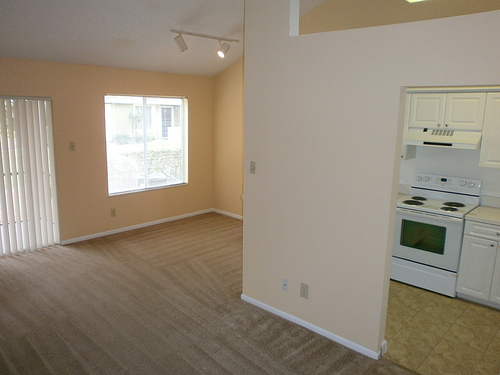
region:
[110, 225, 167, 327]
the floor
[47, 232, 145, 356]
the floor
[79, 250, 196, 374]
the floor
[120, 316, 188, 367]
the floor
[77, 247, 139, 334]
the floor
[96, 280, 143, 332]
the floor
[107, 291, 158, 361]
the floor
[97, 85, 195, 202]
a window on the wall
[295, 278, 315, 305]
an electrical socket on the wall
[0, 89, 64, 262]
a doorway in the room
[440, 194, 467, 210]
a black burner on the stove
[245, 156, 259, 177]
a light switch on the wall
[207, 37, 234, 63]
a lit ceiling light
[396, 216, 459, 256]
an oven window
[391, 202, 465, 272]
an oven door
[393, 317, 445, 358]
a brown floor tile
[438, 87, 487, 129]
a white wooden cabinet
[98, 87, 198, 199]
a glass window on the wall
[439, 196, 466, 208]
a burner on the stove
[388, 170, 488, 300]
a white metal oven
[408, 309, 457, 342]
a brown floor tile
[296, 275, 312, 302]
an electrical socket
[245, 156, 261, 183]
a white light switch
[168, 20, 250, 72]
a pair of ceiling lights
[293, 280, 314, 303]
an off white electrical outlet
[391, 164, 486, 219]
a white electric range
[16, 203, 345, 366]
a newly vacuumed carpet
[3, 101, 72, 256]
a set of white blinds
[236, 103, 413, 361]
a pale peach wall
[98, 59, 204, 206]
a large square window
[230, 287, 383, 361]
a clean white baseboard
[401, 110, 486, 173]
a white oven hood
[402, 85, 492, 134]
a pair of cupboards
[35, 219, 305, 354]
The flooring is brown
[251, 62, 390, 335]
The walls are tan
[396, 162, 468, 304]
The oven is white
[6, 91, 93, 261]
The blinds are long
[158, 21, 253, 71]
Two lights on the ceiling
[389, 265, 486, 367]
Beige tile in the kitchen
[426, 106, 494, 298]
White cabinets in the kitchen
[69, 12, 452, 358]
The inside of a house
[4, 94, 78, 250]
The blinds are white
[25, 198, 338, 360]
There is carpet in the room